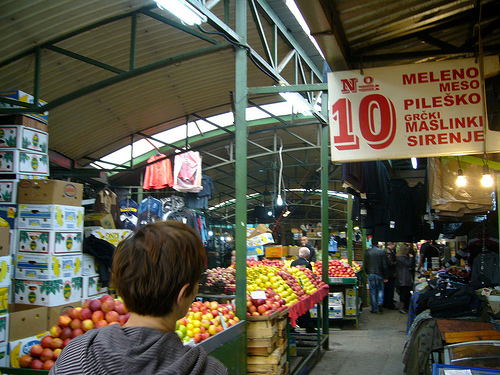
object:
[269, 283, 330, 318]
table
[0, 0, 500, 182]
building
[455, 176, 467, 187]
bulb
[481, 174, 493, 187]
bulb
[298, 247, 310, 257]
hair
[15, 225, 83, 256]
box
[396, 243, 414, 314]
man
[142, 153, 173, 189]
clothes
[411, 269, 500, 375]
table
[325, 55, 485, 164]
sign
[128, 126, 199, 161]
wall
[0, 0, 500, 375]
market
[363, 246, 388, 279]
jacket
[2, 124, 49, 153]
box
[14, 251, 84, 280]
box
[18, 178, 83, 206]
box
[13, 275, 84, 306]
box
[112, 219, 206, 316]
short hair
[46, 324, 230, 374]
hoodie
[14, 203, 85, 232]
bins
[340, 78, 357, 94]
red letter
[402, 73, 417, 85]
red letter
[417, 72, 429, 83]
red letter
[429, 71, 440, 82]
red letter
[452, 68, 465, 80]
red letter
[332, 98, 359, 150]
red number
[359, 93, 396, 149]
red number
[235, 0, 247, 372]
board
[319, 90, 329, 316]
board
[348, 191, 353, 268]
board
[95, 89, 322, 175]
skylight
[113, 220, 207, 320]
head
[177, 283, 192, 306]
ear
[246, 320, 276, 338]
box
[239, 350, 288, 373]
box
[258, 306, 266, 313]
peach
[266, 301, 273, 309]
peach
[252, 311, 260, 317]
peach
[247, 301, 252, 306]
peach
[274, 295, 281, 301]
peach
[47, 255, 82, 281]
bananas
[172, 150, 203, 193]
shirt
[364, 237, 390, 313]
man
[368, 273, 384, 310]
jeans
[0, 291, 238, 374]
apples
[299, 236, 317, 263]
man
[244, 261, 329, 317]
fruit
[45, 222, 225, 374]
person